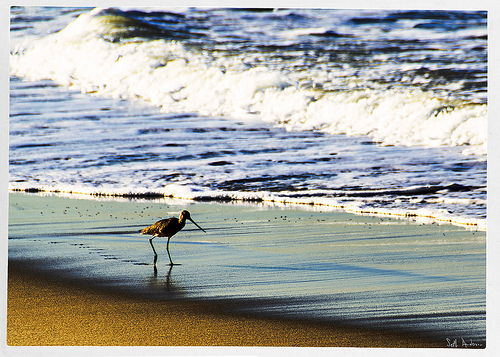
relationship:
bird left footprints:
[132, 190, 206, 270] [58, 229, 154, 290]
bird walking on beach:
[119, 213, 233, 280] [26, 240, 455, 338]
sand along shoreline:
[48, 268, 355, 340] [48, 211, 431, 341]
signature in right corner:
[413, 317, 489, 355] [421, 310, 493, 355]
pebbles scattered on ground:
[41, 179, 364, 226] [28, 151, 393, 278]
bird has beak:
[137, 186, 218, 287] [181, 208, 215, 235]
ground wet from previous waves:
[202, 193, 467, 349] [224, 266, 467, 342]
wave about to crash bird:
[139, 39, 419, 148] [112, 180, 246, 283]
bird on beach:
[139, 209, 206, 270] [57, 213, 460, 336]